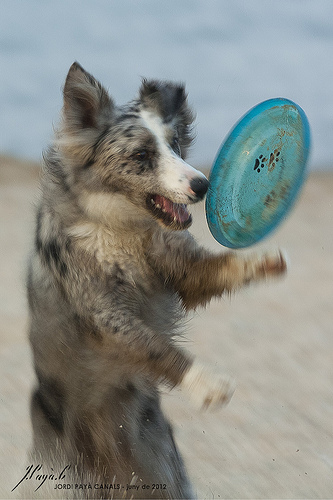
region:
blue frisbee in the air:
[201, 80, 312, 259]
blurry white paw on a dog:
[177, 341, 236, 422]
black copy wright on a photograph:
[16, 445, 172, 498]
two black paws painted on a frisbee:
[252, 135, 290, 174]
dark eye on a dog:
[126, 138, 152, 165]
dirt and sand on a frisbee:
[269, 113, 297, 148]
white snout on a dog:
[149, 144, 206, 222]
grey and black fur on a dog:
[46, 238, 130, 404]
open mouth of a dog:
[149, 198, 190, 226]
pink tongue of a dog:
[160, 200, 178, 214]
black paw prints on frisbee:
[243, 152, 268, 175]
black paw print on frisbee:
[267, 149, 284, 167]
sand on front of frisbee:
[235, 112, 300, 200]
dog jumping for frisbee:
[15, 82, 305, 477]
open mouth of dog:
[141, 167, 212, 223]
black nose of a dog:
[191, 175, 208, 191]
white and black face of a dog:
[115, 102, 188, 190]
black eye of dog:
[135, 148, 146, 161]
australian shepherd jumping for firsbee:
[18, 90, 304, 449]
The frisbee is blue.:
[199, 99, 306, 248]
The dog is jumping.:
[42, 73, 227, 434]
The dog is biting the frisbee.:
[26, 80, 326, 281]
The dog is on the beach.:
[10, 100, 325, 492]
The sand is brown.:
[169, 301, 320, 477]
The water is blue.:
[3, 5, 330, 170]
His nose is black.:
[185, 177, 208, 193]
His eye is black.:
[124, 143, 153, 171]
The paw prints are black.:
[246, 150, 287, 174]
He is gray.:
[42, 60, 232, 489]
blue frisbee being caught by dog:
[207, 92, 319, 247]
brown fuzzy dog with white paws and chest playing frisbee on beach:
[16, 44, 286, 494]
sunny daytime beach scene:
[2, 0, 332, 496]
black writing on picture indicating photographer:
[12, 459, 173, 495]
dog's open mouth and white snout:
[141, 116, 212, 230]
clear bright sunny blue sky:
[5, 0, 325, 172]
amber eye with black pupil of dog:
[122, 144, 161, 165]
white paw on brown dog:
[180, 355, 241, 416]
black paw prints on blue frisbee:
[247, 145, 285, 174]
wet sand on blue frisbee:
[208, 94, 318, 247]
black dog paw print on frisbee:
[249, 151, 266, 173]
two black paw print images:
[249, 140, 291, 180]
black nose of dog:
[192, 176, 209, 190]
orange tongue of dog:
[176, 205, 185, 220]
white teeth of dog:
[149, 199, 161, 210]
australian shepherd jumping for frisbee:
[15, 64, 314, 429]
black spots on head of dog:
[116, 113, 138, 139]